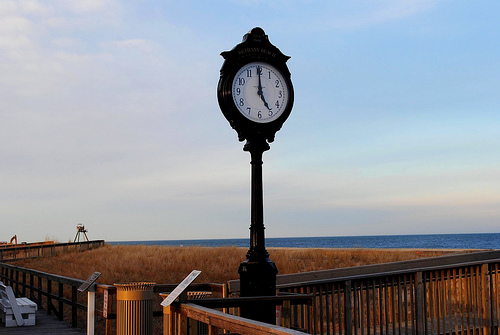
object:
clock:
[218, 24, 301, 329]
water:
[108, 234, 499, 250]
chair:
[1, 282, 38, 329]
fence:
[3, 244, 499, 335]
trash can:
[110, 278, 155, 334]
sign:
[162, 264, 202, 308]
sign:
[76, 272, 106, 293]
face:
[231, 60, 289, 123]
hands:
[254, 67, 273, 115]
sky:
[1, 3, 496, 244]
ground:
[2, 232, 497, 333]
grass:
[29, 241, 470, 277]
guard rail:
[6, 262, 114, 325]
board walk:
[2, 238, 497, 334]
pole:
[239, 140, 281, 324]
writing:
[236, 46, 284, 58]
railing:
[167, 291, 321, 334]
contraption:
[72, 222, 92, 244]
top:
[72, 222, 89, 234]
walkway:
[151, 245, 500, 332]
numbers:
[234, 68, 284, 122]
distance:
[1, 155, 491, 264]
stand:
[233, 256, 279, 325]